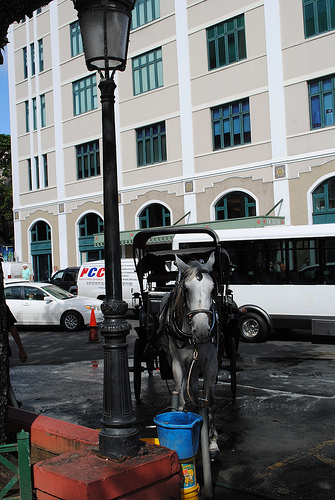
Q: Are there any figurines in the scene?
A: No, there are no figurines.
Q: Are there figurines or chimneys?
A: No, there are no figurines or chimneys.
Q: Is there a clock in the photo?
A: No, there are no clocks.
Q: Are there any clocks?
A: No, there are no clocks.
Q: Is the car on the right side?
A: No, the car is on the left of the image.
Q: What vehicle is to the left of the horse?
A: The vehicle is a car.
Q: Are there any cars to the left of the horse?
A: Yes, there is a car to the left of the horse.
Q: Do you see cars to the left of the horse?
A: Yes, there is a car to the left of the horse.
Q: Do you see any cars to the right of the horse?
A: No, the car is to the left of the horse.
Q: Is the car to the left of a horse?
A: Yes, the car is to the left of a horse.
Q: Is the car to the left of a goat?
A: No, the car is to the left of a horse.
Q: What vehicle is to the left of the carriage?
A: The vehicle is a car.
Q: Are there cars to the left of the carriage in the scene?
A: Yes, there is a car to the left of the carriage.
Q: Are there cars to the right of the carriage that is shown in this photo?
A: No, the car is to the left of the carriage.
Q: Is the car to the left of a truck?
A: No, the car is to the left of the carriage.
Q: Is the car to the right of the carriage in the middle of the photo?
A: No, the car is to the left of the carriage.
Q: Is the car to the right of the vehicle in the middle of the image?
A: No, the car is to the left of the carriage.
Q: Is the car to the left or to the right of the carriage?
A: The car is to the left of the carriage.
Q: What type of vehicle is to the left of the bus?
A: The vehicle is a car.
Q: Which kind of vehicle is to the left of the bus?
A: The vehicle is a car.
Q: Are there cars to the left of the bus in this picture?
A: Yes, there is a car to the left of the bus.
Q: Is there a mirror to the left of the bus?
A: No, there is a car to the left of the bus.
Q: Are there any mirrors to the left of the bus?
A: No, there is a car to the left of the bus.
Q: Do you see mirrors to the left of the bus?
A: No, there is a car to the left of the bus.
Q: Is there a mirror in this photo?
A: No, there are no mirrors.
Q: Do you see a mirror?
A: No, there are no mirrors.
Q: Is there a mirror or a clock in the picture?
A: No, there are no mirrors or clocks.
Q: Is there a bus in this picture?
A: Yes, there is a bus.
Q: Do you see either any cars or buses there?
A: Yes, there is a bus.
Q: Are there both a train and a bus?
A: No, there is a bus but no trains.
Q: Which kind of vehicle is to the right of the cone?
A: The vehicle is a bus.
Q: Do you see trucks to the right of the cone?
A: No, there is a bus to the right of the cone.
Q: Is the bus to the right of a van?
A: No, the bus is to the right of the traffic cone.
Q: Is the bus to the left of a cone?
A: No, the bus is to the right of a cone.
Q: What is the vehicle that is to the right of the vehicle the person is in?
A: The vehicle is a bus.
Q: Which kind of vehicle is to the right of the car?
A: The vehicle is a bus.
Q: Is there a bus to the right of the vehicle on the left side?
A: Yes, there is a bus to the right of the car.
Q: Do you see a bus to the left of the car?
A: No, the bus is to the right of the car.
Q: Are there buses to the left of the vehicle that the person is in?
A: No, the bus is to the right of the car.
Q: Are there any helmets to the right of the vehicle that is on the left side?
A: No, there is a bus to the right of the car.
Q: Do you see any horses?
A: Yes, there is a horse.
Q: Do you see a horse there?
A: Yes, there is a horse.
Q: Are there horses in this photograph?
A: Yes, there is a horse.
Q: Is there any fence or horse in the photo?
A: Yes, there is a horse.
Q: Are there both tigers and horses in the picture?
A: No, there is a horse but no tigers.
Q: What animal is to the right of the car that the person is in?
A: The animal is a horse.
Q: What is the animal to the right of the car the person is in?
A: The animal is a horse.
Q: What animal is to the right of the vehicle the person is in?
A: The animal is a horse.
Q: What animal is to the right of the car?
A: The animal is a horse.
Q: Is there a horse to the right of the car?
A: Yes, there is a horse to the right of the car.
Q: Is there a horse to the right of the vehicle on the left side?
A: Yes, there is a horse to the right of the car.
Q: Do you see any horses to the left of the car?
A: No, the horse is to the right of the car.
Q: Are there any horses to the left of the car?
A: No, the horse is to the right of the car.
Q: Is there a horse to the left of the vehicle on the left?
A: No, the horse is to the right of the car.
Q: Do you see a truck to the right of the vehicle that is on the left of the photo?
A: No, there is a horse to the right of the car.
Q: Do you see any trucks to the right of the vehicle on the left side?
A: No, there is a horse to the right of the car.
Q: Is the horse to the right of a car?
A: Yes, the horse is to the right of a car.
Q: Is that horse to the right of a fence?
A: No, the horse is to the right of a car.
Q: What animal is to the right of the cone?
A: The animal is a horse.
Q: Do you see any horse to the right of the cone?
A: Yes, there is a horse to the right of the cone.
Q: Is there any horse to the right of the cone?
A: Yes, there is a horse to the right of the cone.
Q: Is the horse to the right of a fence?
A: No, the horse is to the right of the cone.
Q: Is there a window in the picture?
A: Yes, there are windows.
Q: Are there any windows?
A: Yes, there are windows.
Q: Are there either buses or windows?
A: Yes, there are windows.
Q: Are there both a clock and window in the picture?
A: No, there are windows but no clocks.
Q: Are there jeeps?
A: No, there are no jeeps.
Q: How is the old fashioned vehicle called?
A: The vehicle is a carriage.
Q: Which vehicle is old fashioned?
A: The vehicle is a carriage.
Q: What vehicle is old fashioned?
A: The vehicle is a carriage.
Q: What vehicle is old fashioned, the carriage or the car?
A: The carriage is old fashioned.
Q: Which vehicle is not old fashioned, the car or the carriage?
A: The car is not old fashioned.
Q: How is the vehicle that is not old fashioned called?
A: The vehicle is a car.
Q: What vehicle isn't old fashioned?
A: The vehicle is a car.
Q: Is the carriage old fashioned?
A: Yes, the carriage is old fashioned.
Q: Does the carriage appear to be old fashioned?
A: Yes, the carriage is old fashioned.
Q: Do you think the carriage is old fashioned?
A: Yes, the carriage is old fashioned.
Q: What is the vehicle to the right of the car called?
A: The vehicle is a carriage.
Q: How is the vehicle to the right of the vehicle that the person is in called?
A: The vehicle is a carriage.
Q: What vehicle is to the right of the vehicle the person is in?
A: The vehicle is a carriage.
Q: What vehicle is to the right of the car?
A: The vehicle is a carriage.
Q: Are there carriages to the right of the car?
A: Yes, there is a carriage to the right of the car.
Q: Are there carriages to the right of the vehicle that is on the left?
A: Yes, there is a carriage to the right of the car.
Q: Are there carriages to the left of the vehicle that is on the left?
A: No, the carriage is to the right of the car.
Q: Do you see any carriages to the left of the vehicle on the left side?
A: No, the carriage is to the right of the car.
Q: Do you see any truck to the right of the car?
A: No, there is a carriage to the right of the car.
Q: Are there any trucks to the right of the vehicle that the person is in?
A: No, there is a carriage to the right of the car.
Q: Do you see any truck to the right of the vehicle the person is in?
A: No, there is a carriage to the right of the car.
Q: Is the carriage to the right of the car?
A: Yes, the carriage is to the right of the car.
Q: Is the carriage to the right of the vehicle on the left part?
A: Yes, the carriage is to the right of the car.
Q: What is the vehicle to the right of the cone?
A: The vehicle is a carriage.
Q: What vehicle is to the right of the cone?
A: The vehicle is a carriage.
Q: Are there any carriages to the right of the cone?
A: Yes, there is a carriage to the right of the cone.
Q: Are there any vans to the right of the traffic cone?
A: No, there is a carriage to the right of the traffic cone.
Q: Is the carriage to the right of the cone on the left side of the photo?
A: Yes, the carriage is to the right of the traffic cone.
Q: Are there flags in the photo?
A: No, there are no flags.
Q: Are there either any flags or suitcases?
A: No, there are no flags or suitcases.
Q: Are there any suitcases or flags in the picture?
A: No, there are no flags or suitcases.